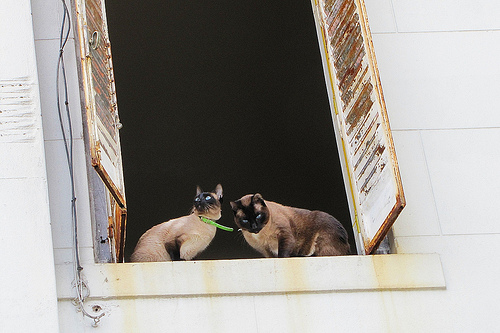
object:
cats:
[130, 183, 349, 265]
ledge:
[88, 254, 447, 299]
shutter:
[331, 43, 373, 130]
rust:
[326, 19, 356, 35]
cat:
[129, 183, 224, 263]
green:
[200, 217, 234, 231]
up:
[193, 183, 224, 215]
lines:
[53, 0, 87, 295]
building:
[348, 0, 498, 333]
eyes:
[195, 196, 212, 202]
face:
[234, 205, 270, 232]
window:
[91, 0, 362, 266]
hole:
[18, 84, 22, 87]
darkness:
[102, 0, 357, 262]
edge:
[111, 254, 365, 268]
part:
[89, 129, 128, 259]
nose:
[251, 223, 258, 230]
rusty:
[333, 34, 359, 55]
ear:
[214, 183, 223, 198]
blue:
[207, 196, 210, 200]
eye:
[256, 213, 262, 219]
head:
[230, 193, 270, 231]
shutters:
[335, 42, 375, 171]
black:
[246, 206, 256, 217]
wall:
[102, 270, 138, 293]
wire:
[53, 0, 83, 310]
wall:
[429, 134, 480, 213]